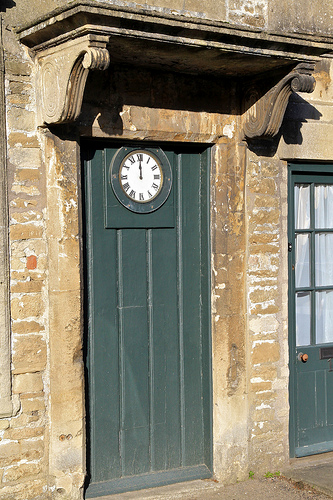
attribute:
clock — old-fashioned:
[115, 150, 168, 203]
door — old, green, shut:
[83, 140, 211, 495]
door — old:
[289, 167, 331, 461]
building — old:
[0, 0, 332, 497]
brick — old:
[8, 224, 49, 245]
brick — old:
[13, 293, 44, 319]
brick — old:
[7, 130, 42, 150]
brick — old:
[253, 210, 283, 228]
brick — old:
[250, 232, 282, 245]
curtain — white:
[293, 184, 331, 346]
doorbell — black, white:
[287, 243, 292, 253]